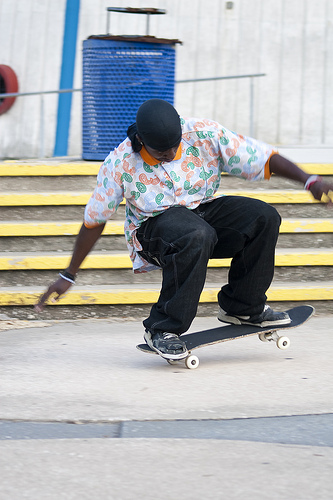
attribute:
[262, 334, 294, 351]
wheels — white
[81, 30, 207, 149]
trashcan — blue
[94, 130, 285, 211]
shirt — printed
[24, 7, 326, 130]
building — metal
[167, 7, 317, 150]
wall — white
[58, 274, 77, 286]
band — white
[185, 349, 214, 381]
wheel — small, white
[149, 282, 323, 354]
skateboard — black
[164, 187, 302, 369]
pants — black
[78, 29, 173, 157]
trash can — blue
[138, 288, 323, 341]
skateboard — black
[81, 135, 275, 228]
shirt — white, floral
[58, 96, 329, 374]
boy — black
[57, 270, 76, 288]
bracelet — white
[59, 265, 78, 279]
bracelet — black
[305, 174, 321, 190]
bracelet — orange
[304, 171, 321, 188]
bracelet — white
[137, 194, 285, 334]
jeans — black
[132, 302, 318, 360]
skateboard — black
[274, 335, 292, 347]
wheel — white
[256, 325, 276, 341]
wheel — white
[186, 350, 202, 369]
wheel — white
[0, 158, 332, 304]
steps — yellow and gray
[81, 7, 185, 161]
trash can — blue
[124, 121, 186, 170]
collar — orange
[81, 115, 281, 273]
shirt — white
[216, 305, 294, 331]
shoe — dark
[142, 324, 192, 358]
shoe — dark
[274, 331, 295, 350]
wheel — white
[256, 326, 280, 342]
wheel — white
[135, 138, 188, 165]
collar — orange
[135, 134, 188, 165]
collar — orange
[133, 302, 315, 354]
skateboard — black